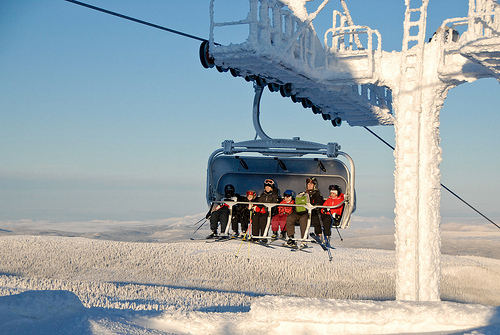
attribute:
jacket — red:
[316, 193, 345, 215]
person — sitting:
[284, 174, 321, 251]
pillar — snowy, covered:
[387, 81, 448, 303]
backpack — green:
[294, 190, 310, 215]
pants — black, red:
[269, 215, 289, 235]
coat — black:
[256, 188, 278, 208]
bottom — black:
[250, 208, 270, 242]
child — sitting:
[235, 191, 256, 233]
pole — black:
[333, 217, 344, 243]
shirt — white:
[215, 194, 237, 209]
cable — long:
[67, 0, 214, 47]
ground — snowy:
[6, 300, 499, 334]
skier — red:
[285, 172, 319, 248]